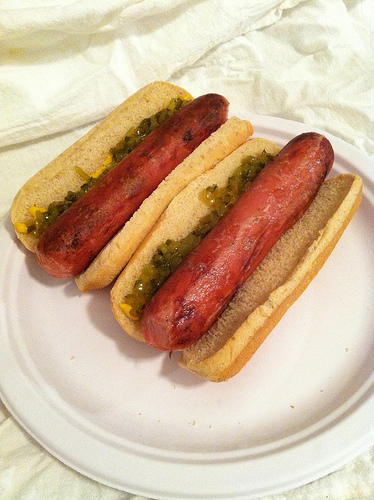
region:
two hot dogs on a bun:
[4, 72, 369, 388]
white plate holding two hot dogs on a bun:
[2, 106, 373, 494]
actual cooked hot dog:
[134, 126, 338, 355]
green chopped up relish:
[115, 134, 280, 326]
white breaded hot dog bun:
[103, 126, 363, 392]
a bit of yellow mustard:
[8, 140, 120, 244]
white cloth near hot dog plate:
[5, 6, 373, 104]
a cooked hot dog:
[28, 82, 235, 285]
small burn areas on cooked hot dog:
[176, 125, 197, 146]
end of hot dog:
[131, 305, 205, 362]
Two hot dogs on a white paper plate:
[1, 79, 372, 498]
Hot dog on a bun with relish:
[109, 130, 363, 383]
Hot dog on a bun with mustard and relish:
[9, 79, 253, 292]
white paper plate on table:
[0, 111, 373, 498]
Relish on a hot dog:
[124, 146, 274, 310]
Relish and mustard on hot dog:
[14, 94, 189, 237]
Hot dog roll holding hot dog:
[107, 138, 365, 383]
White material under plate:
[1, 0, 368, 199]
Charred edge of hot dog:
[293, 131, 324, 145]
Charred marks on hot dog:
[181, 93, 227, 152]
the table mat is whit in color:
[13, 440, 75, 492]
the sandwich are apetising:
[83, 164, 319, 354]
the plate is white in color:
[129, 379, 318, 485]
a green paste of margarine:
[147, 176, 250, 257]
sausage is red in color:
[171, 224, 245, 321]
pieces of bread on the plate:
[143, 389, 233, 441]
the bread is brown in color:
[232, 238, 336, 309]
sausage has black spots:
[162, 108, 227, 141]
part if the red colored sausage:
[96, 189, 156, 225]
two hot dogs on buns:
[9, 79, 363, 380]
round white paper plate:
[1, 216, 370, 499]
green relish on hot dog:
[127, 149, 276, 324]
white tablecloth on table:
[2, 0, 371, 81]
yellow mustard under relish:
[77, 153, 113, 180]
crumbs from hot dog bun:
[283, 343, 352, 412]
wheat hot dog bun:
[110, 136, 363, 383]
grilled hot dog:
[39, 92, 230, 280]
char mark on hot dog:
[179, 129, 193, 144]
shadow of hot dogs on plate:
[8, 233, 204, 388]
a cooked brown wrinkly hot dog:
[33, 89, 239, 268]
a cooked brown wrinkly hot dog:
[140, 128, 337, 344]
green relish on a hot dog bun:
[16, 96, 211, 241]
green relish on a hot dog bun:
[125, 148, 284, 321]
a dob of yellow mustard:
[14, 217, 30, 238]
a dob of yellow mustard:
[115, 298, 140, 324]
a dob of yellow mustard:
[87, 149, 116, 184]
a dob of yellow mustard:
[175, 88, 189, 105]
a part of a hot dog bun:
[162, 172, 360, 379]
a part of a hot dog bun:
[110, 136, 294, 336]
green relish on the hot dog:
[131, 277, 144, 290]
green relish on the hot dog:
[147, 274, 158, 285]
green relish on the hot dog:
[156, 242, 166, 253]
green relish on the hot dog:
[203, 180, 214, 188]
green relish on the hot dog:
[136, 112, 148, 126]